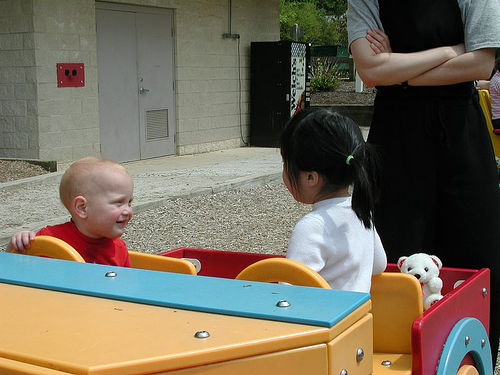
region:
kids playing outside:
[59, 87, 384, 297]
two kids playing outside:
[34, 77, 431, 368]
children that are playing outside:
[14, 22, 446, 374]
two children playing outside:
[47, 73, 497, 300]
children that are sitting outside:
[48, 91, 393, 324]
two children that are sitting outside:
[48, 53, 443, 361]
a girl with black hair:
[262, 112, 422, 239]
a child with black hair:
[308, 130, 428, 236]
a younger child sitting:
[14, 141, 144, 251]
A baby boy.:
[36, 158, 145, 266]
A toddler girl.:
[281, 98, 391, 300]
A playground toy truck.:
[1, 244, 493, 374]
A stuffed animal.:
[396, 251, 448, 308]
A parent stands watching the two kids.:
[346, 0, 498, 126]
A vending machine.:
[250, 41, 308, 145]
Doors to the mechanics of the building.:
[94, 0, 184, 163]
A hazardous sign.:
[55, 63, 87, 88]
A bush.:
[311, 59, 342, 89]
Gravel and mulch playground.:
[201, 198, 272, 248]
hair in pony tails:
[343, 133, 380, 228]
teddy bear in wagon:
[399, 252, 445, 316]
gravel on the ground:
[189, 200, 278, 245]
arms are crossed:
[353, 32, 492, 92]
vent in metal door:
[143, 107, 173, 146]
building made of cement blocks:
[43, 92, 93, 143]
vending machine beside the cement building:
[249, 37, 312, 147]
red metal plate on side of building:
[55, 60, 87, 87]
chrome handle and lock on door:
[137, 77, 154, 95]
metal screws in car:
[276, 298, 293, 310]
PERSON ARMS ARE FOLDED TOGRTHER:
[371, 52, 452, 82]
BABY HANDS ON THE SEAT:
[12, 233, 28, 256]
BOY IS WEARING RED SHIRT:
[100, 245, 121, 255]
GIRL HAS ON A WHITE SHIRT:
[330, 221, 362, 278]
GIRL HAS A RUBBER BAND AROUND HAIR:
[342, 154, 357, 164]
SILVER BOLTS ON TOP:
[195, 324, 209, 340]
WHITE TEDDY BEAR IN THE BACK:
[396, 253, 451, 288]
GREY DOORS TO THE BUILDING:
[116, 96, 123, 139]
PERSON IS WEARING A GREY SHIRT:
[476, 17, 488, 37]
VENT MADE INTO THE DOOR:
[149, 109, 165, 138]